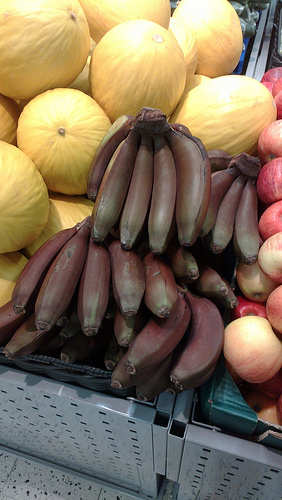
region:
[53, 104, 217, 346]
red bananas at a fruit stand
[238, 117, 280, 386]
red apples at a fruit stand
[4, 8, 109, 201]
yellow melons at a fruit stand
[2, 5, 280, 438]
fruit at a fruit stand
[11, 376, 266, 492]
metal bins at a fruit stand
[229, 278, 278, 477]
red apples in a green box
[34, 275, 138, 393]
red bananas in a black basket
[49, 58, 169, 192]
yellow melons behind black bananas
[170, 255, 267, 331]
red apples beside red bananas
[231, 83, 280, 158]
yellow melons beside red apples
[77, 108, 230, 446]
lots of bananas on the shelf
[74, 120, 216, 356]
the bananas are brown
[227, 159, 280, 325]
apples sitting next to bananas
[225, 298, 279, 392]
the apples are red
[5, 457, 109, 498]
ground is tile floor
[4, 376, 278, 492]
fruit sitting on silver shelving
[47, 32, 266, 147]
some sort of circular fruit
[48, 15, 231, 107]
fruit is a creme color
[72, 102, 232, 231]
bananas come in bunches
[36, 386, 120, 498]
shelves have little holes in them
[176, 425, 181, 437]
black hole is spotted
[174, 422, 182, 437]
black hole is spotted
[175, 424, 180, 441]
black hole is spotted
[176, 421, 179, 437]
black hole is spotted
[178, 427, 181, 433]
black hole is spotted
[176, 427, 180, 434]
black hole is spotted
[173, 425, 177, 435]
black hole is spotted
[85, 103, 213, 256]
cluster of brown bananas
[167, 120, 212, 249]
brown banana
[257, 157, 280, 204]
red ripe apple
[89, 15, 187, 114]
single yellow squash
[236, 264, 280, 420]
a few red ripe apples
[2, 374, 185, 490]
side of a storage container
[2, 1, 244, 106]
a bunch of yellow squash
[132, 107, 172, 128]
stem of banana bunch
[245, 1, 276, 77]
sides of two storage containers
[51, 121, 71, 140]
stem of a yellow squash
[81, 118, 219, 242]
brown and green bananas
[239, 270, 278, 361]
pile of red apples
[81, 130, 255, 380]
many bunches of bananas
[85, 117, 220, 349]
bunches of brown bananas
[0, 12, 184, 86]
pile of yellow melons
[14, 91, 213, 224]
melon next to banana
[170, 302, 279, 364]
apple and a banana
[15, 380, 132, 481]
metal case holding fruit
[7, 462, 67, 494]
white and black tile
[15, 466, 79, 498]
white tile with black spots